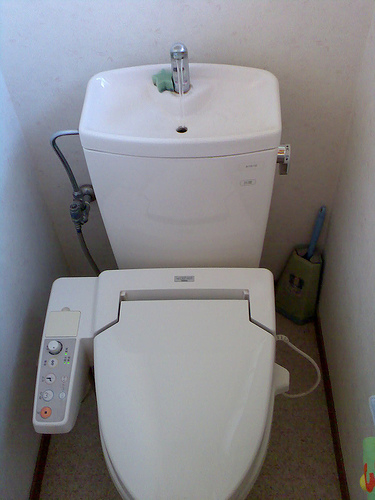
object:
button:
[40, 406, 52, 420]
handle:
[307, 204, 326, 257]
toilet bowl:
[49, 43, 290, 269]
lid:
[79, 63, 282, 160]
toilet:
[30, 43, 322, 500]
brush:
[307, 205, 326, 260]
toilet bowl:
[92, 263, 290, 499]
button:
[45, 373, 56, 385]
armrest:
[32, 276, 98, 435]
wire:
[275, 334, 321, 399]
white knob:
[48, 340, 62, 355]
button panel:
[36, 339, 76, 423]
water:
[176, 59, 185, 131]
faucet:
[170, 43, 193, 97]